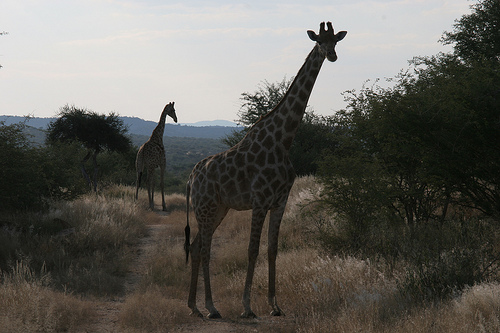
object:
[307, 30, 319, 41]
ear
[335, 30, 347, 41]
ear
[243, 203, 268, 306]
legs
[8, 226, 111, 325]
grass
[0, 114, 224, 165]
mountains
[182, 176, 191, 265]
tail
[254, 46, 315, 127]
mane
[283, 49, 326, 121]
neck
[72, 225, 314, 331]
ground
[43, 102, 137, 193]
tree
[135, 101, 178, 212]
brown giraffe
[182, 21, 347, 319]
brown giraffe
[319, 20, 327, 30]
horn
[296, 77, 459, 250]
trees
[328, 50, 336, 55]
nose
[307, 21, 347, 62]
head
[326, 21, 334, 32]
horns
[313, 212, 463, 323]
foreground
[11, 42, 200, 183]
distant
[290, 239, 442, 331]
grass